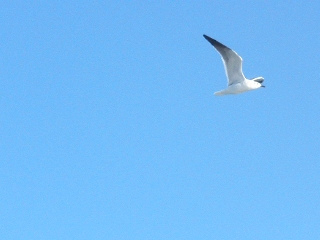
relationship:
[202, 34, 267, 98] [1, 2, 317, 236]
bird in sky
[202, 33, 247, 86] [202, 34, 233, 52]
wing has tip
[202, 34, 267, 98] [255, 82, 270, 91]
bird has head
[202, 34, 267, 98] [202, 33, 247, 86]
bird has wing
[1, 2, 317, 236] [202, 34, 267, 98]
sky behind bird